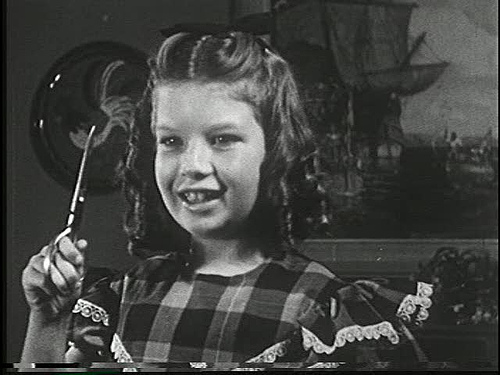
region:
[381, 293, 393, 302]
part of a shirt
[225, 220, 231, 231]
part of a chin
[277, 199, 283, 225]
part of a hair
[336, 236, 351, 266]
part of a trouser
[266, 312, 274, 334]
part of a neck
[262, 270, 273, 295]
edge of a shirt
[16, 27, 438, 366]
young girl in a plaid dress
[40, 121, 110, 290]
large pair of shiny scissors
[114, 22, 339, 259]
curly brown hair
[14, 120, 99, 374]
girl's right hand holding a pair of scissors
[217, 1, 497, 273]
painting of a large sail boat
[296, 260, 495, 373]
top edge of a mantle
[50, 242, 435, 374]
plaid dress with white lace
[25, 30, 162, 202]
round painting of a rooster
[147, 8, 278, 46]
hair bow on a girl's head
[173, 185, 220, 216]
girl's buck toothed smile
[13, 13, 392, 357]
a girl holding a pair of scissors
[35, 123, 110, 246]
a pair of scissors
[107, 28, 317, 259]
the head of a girl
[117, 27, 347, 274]
a girl with curly hair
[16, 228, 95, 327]
the hand of a girl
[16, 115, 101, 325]
a hand holding a pair of scissors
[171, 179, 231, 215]
the mouth of a girl who is smiling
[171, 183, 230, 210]
the mouth of a girl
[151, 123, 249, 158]
the eyes of a girl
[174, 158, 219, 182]
the nose of a girl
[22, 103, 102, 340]
scissors in girls hand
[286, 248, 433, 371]
lace ruffle on shirt sleeve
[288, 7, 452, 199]
picture of ship on wall behind girl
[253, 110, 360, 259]
curly hair of girl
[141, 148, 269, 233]
big bright smile of girl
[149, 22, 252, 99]
part in girl's hair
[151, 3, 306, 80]
ribbon tied in girl's hair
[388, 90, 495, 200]
small boat in picture behind girl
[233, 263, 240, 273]
part of a neck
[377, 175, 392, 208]
part of a board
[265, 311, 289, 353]
part of a shirt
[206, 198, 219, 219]
part of a mouth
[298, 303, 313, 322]
part of a shirt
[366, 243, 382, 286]
part of a board